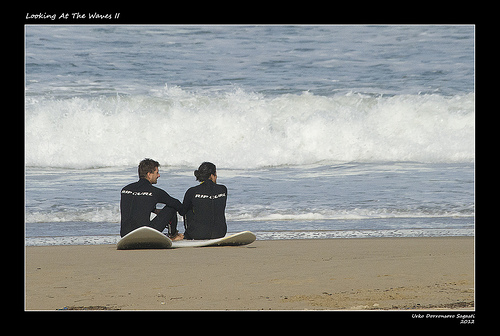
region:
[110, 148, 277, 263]
Two people are sitting.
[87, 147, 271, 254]
Two people are sitting on surfboards.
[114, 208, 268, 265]
The surfboards are white.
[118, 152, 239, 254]
The people are wearing wetsuits.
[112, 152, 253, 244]
The wetsuits are black.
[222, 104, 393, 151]
The wave is white.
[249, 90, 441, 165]
The water has waves in it.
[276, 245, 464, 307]
The beach is sand.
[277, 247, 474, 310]
The sand is brown.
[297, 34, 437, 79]
The water is blue.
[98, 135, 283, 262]
two people sitting on surfboards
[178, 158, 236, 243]
a woman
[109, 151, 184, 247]
a man with his knees bent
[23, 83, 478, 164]
large white wave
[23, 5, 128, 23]
title of the photograph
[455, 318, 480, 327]
year picture was taken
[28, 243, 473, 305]
strip of sand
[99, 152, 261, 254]
two people in black wetsuits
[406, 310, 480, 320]
photographer's name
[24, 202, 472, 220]
wave rolling into the shore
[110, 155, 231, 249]
a couple is sitting on the beach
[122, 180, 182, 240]
the man is wearing a full wetsuit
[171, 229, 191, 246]
the man is barefoot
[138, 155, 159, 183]
the man has brown hair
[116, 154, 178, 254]
the man is sitting on a surfboard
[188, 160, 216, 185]
the girl has brown hair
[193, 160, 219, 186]
the has her hair in a ponytail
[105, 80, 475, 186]
the couple is looking at the surf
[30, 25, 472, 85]
the ocean has a slight chop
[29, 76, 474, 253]
a wave is breaking on the shore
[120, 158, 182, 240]
a surfer wearing a black wetsuit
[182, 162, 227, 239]
a woman wearing a black wetsuit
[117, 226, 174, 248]
the man is sitting on a white surfboard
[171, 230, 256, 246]
the woman is sitting on a white surfboard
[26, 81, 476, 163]
white water from the waves crashing onto the surface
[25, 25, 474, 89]
calm blue ocean water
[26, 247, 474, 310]
wet hard packed beach sand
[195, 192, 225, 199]
white letters written on the back of the wetsuits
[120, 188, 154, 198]
the name of the brand of the wetsuit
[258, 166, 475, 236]
calm water at the shoreline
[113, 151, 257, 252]
The surfers on the beach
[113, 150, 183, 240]
The male surfer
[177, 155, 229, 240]
The female surfer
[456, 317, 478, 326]
The year the photo was taken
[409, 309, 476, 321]
The information of the photographer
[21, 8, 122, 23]
The title of the photo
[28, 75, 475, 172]
The large wave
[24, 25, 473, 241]
The ocean in front of the people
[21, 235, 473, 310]
The sand of the beach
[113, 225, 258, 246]
The surfboards on the sand